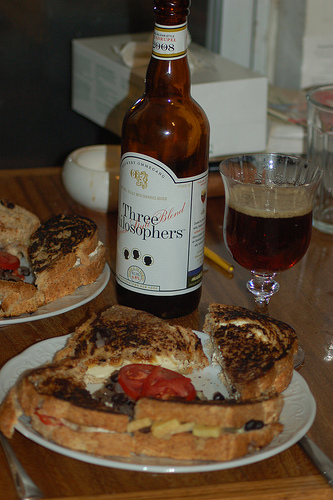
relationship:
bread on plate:
[207, 301, 307, 401] [0, 324, 317, 477]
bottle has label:
[109, 4, 212, 314] [113, 147, 206, 297]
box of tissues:
[69, 31, 282, 160] [111, 27, 175, 75]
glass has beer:
[217, 152, 321, 331] [224, 194, 314, 276]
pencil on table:
[203, 239, 235, 281] [5, 158, 330, 499]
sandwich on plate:
[21, 293, 300, 470] [0, 324, 317, 477]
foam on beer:
[226, 184, 311, 220] [224, 194, 314, 276]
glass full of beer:
[217, 152, 321, 331] [224, 194, 314, 276]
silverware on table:
[2, 426, 46, 497] [5, 158, 330, 499]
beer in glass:
[224, 194, 314, 276] [217, 152, 321, 331]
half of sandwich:
[28, 360, 284, 459] [21, 293, 300, 470]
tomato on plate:
[114, 359, 191, 401] [0, 324, 317, 477]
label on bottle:
[113, 147, 206, 297] [109, 4, 212, 314]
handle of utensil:
[299, 433, 332, 474] [291, 421, 331, 485]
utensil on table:
[291, 421, 331, 485] [5, 158, 330, 499]